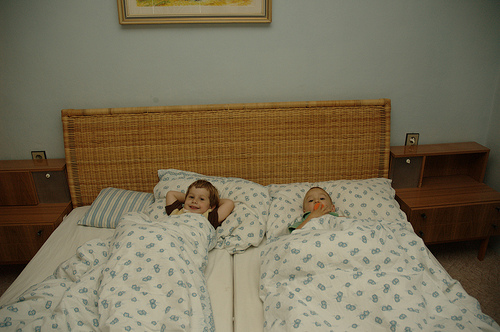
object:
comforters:
[0, 168, 499, 332]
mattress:
[204, 238, 267, 332]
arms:
[165, 190, 234, 222]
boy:
[165, 179, 235, 230]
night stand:
[0, 157, 72, 266]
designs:
[122, 259, 166, 295]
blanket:
[0, 204, 265, 332]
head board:
[60, 98, 392, 208]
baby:
[288, 187, 348, 234]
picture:
[405, 133, 420, 147]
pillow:
[77, 187, 154, 229]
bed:
[0, 98, 500, 332]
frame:
[117, 0, 274, 26]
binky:
[314, 203, 329, 214]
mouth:
[314, 205, 325, 213]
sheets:
[258, 219, 500, 332]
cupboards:
[388, 142, 498, 261]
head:
[184, 179, 219, 214]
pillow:
[265, 178, 408, 244]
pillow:
[144, 168, 270, 247]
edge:
[122, 20, 274, 28]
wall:
[13, 27, 439, 90]